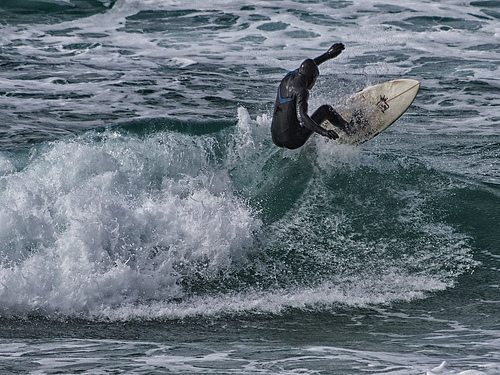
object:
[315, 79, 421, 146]
surfboard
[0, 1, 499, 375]
water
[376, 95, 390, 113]
mark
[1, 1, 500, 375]
foam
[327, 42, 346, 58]
hand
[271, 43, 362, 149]
wetsuit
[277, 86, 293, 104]
mark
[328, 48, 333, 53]
reflection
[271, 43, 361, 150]
surfer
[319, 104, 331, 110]
knee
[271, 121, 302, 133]
waist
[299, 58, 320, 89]
head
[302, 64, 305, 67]
reflection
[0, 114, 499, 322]
wave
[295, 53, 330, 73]
left arm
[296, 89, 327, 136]
right arm